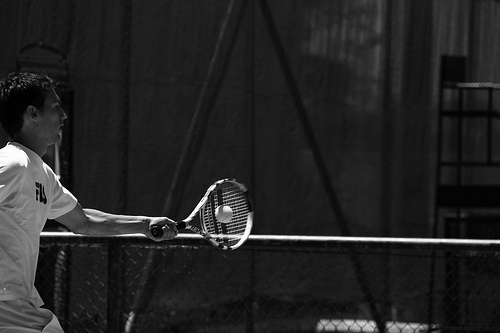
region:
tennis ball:
[212, 200, 237, 230]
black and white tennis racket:
[147, 183, 257, 253]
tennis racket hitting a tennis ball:
[148, 175, 256, 254]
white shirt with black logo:
[0, 153, 85, 306]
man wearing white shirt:
[3, 77, 97, 289]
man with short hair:
[0, 67, 77, 158]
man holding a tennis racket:
[8, 65, 262, 258]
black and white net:
[62, 230, 497, 318]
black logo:
[32, 176, 54, 211]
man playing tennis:
[2, 67, 268, 242]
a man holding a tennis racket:
[15, 68, 255, 248]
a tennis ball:
[200, 197, 245, 238]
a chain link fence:
[319, 229, 464, 330]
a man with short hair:
[11, 65, 76, 151]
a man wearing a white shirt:
[1, 88, 75, 257]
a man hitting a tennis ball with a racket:
[113, 132, 288, 279]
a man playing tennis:
[14, 108, 264, 332]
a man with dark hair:
[0, 64, 69, 161]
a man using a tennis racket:
[67, 162, 260, 267]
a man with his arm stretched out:
[38, 169, 270, 239]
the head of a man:
[0, 65, 77, 150]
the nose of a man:
[56, 103, 74, 121]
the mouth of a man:
[56, 120, 68, 135]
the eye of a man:
[49, 99, 64, 113]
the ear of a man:
[23, 101, 43, 124]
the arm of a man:
[43, 175, 148, 242]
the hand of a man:
[141, 210, 181, 245]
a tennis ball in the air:
[210, 200, 237, 227]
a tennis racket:
[147, 174, 259, 254]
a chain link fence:
[32, 220, 499, 332]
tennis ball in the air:
[212, 205, 232, 225]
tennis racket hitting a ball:
[149, 175, 256, 252]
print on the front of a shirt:
[33, 175, 47, 201]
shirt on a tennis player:
[1, 140, 81, 307]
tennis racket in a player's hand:
[148, 175, 256, 251]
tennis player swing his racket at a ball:
[0, 65, 257, 332]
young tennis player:
[1, 67, 258, 332]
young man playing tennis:
[0, 69, 255, 330]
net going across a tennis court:
[35, 231, 495, 331]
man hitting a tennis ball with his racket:
[1, 62, 256, 331]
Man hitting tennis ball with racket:
[1, 70, 256, 331]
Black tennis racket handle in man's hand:
[146, 217, 179, 241]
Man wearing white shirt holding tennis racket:
[1, 72, 252, 332]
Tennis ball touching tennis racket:
[213, 203, 233, 222]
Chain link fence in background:
[36, 231, 498, 331]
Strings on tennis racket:
[201, 178, 253, 248]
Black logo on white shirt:
[32, 180, 47, 202]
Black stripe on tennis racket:
[241, 187, 254, 213]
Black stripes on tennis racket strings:
[209, 185, 234, 250]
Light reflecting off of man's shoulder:
[0, 142, 28, 175]